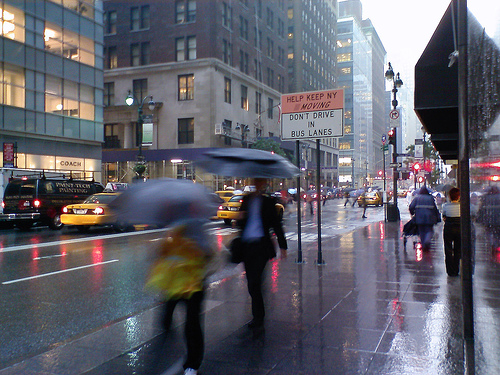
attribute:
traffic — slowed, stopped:
[0, 159, 427, 253]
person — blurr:
[145, 182, 222, 373]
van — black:
[8, 177, 103, 226]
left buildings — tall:
[6, 2, 105, 218]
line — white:
[3, 256, 125, 291]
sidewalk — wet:
[77, 216, 472, 371]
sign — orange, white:
[276, 85, 346, 140]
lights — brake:
[40, 206, 117, 218]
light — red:
[404, 159, 424, 174]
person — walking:
[406, 180, 442, 257]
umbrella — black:
[182, 141, 301, 181]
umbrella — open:
[187, 126, 305, 184]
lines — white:
[6, 251, 129, 284]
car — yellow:
[61, 178, 132, 229]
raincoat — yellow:
[144, 231, 216, 295]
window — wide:
[44, 70, 94, 120]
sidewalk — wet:
[329, 256, 399, 366]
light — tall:
[376, 63, 402, 219]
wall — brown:
[149, 7, 176, 62]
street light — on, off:
[120, 88, 159, 177]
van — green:
[3, 173, 110, 234]